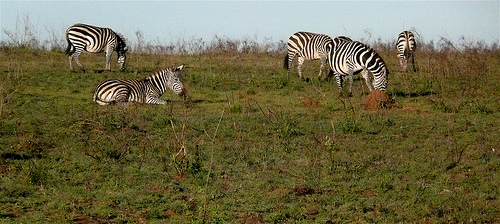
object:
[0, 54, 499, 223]
ground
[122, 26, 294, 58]
sticks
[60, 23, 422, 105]
zebra's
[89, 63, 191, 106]
zebra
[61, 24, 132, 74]
zebra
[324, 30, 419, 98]
zebras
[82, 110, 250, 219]
sticks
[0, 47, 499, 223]
grass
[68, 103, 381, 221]
shrubs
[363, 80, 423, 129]
shrub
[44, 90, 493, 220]
pasture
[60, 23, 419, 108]
zebras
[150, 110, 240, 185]
twigs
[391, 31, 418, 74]
zebra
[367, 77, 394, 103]
head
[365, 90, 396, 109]
dirt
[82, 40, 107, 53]
belly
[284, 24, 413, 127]
zebra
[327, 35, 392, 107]
zebra